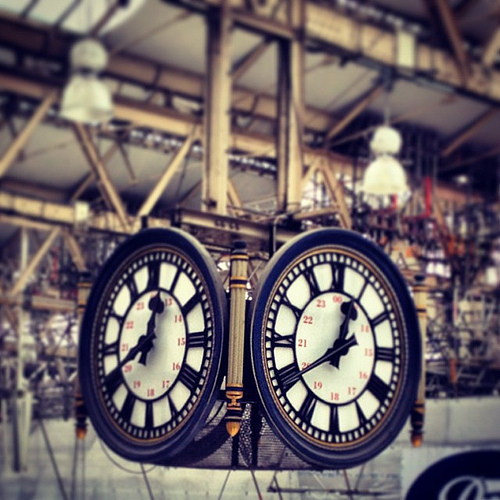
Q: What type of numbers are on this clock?
A: Roman numerals.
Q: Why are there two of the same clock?
A: Duplicates.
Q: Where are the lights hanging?
A: Ceiling.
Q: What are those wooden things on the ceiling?
A: Beams.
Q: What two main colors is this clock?
A: Black and white.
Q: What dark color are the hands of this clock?
A: Black.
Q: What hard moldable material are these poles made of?
A: Metal.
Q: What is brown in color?
A: The poles.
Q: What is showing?
A: Two clocks.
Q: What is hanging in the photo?
A: White objects.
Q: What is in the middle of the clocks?
A: The pillar.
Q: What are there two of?
A: Clocks.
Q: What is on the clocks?
A: Hands.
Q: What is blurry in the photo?
A: The background.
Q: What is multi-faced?
A: The clock.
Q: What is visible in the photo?
A: The clocks.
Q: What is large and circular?
A: The clocks.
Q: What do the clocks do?
A: Tell time.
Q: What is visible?
A: The clocks.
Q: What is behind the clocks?
A: Parts.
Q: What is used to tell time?
A: The clocks.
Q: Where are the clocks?
A: On the ground.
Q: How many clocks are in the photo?
A: Two.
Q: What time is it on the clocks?
A: 12:40 pm.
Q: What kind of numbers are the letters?
A: Roman Numerals.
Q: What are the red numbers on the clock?
A: 24 Hour clock Numbers.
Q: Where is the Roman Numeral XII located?
A: At the top of the clock.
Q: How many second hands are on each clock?
A: Zero.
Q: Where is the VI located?
A: At the bottom of each clock.